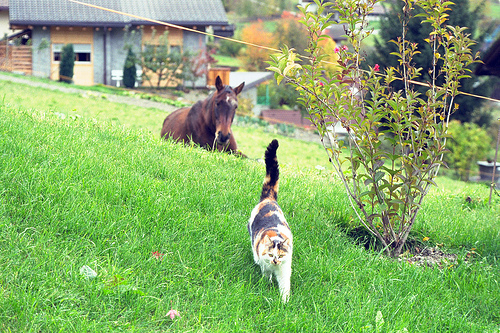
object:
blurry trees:
[231, 3, 497, 164]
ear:
[233, 81, 245, 96]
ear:
[215, 75, 225, 93]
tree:
[354, 0, 500, 144]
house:
[8, 0, 230, 101]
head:
[262, 234, 290, 268]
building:
[0, 3, 234, 113]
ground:
[259, 74, 377, 132]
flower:
[151, 249, 163, 261]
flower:
[163, 307, 180, 319]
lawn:
[2, 78, 497, 331]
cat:
[246, 136, 293, 305]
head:
[213, 75, 246, 146]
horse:
[159, 74, 259, 161]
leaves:
[323, 86, 339, 94]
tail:
[259, 137, 281, 201]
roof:
[7, 2, 228, 29]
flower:
[373, 63, 380, 71]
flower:
[333, 46, 340, 53]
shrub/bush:
[264, 0, 484, 259]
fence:
[0, 43, 34, 74]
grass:
[1, 66, 498, 330]